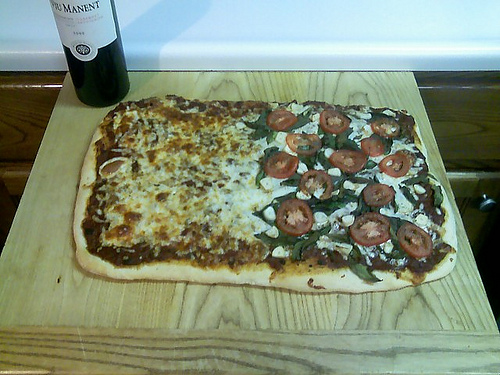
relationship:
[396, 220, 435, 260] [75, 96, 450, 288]
tomato on pizza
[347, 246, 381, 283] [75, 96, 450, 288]
greens on pizza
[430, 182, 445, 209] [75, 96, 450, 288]
greens on pizza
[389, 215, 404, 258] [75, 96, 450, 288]
greens on pizza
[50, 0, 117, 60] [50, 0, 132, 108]
label on bottle bottle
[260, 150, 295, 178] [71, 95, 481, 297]
tomato on pizza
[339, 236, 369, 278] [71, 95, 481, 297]
greens on pizza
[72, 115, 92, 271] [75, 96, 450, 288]
crust on pizza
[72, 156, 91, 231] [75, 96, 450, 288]
crust on pizza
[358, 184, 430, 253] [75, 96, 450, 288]
tomatoes on pizza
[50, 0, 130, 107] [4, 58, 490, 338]
bottle on board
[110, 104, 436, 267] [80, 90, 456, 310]
cheese on pizza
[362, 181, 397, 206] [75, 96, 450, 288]
tomato on pizza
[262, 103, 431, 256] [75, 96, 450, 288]
nuts on pizza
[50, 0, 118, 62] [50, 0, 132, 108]
label on bottle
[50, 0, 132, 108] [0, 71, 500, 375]
bottle on board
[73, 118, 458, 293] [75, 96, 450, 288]
brown crust on pizza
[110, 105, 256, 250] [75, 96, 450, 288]
yellow cheese on pizza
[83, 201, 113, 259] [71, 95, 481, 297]
sauce on pizza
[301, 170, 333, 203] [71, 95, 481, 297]
tomato on pizza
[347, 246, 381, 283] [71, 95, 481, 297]
greens on pizza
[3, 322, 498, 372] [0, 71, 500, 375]
seam joins together board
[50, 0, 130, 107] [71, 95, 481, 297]
bottle near pizza